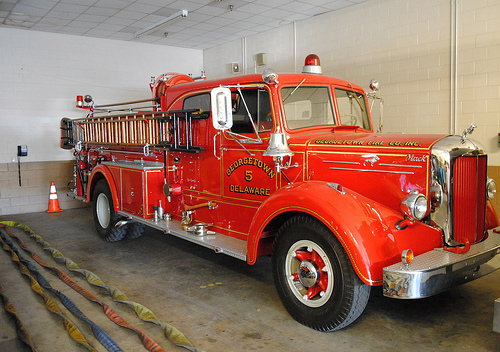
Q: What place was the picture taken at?
A: It was taken at the garage.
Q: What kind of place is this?
A: It is a garage.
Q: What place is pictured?
A: It is a garage.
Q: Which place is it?
A: It is a garage.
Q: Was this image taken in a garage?
A: Yes, it was taken in a garage.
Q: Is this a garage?
A: Yes, it is a garage.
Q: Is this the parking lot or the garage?
A: It is the garage.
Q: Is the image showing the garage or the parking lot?
A: It is showing the garage.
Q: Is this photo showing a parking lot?
A: No, the picture is showing a garage.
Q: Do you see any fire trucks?
A: Yes, there is a fire truck.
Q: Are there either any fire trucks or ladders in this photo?
A: Yes, there is a fire truck.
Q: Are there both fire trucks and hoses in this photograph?
A: Yes, there are both a fire truck and a hose.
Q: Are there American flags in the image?
A: No, there are no American flags.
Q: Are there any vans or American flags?
A: No, there are no American flags or vans.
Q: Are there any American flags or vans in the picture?
A: No, there are no American flags or vans.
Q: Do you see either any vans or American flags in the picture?
A: No, there are no American flags or vans.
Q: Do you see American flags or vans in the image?
A: No, there are no American flags or vans.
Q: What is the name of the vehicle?
A: The vehicle is a fire truck.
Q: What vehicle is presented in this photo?
A: The vehicle is a fire truck.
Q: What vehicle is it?
A: The vehicle is a fire truck.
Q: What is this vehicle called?
A: This is a fire truck.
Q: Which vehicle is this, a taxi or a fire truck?
A: This is a fire truck.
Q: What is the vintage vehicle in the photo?
A: The vehicle is a fire truck.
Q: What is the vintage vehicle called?
A: The vehicle is a fire truck.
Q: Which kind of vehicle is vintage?
A: The vehicle is a fire truck.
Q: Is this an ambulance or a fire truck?
A: This is a fire truck.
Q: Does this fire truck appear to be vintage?
A: Yes, the fire truck is vintage.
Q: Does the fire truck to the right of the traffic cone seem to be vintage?
A: Yes, the fire truck is vintage.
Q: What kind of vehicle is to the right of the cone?
A: The vehicle is a fire truck.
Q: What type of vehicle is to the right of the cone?
A: The vehicle is a fire truck.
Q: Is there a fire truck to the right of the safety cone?
A: Yes, there is a fire truck to the right of the safety cone.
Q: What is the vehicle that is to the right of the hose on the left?
A: The vehicle is a fire truck.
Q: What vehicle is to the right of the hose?
A: The vehicle is a fire truck.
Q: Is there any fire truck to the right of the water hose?
A: Yes, there is a fire truck to the right of the water hose.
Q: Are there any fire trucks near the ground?
A: Yes, there is a fire truck near the ground.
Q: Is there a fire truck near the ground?
A: Yes, there is a fire truck near the ground.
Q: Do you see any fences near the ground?
A: No, there is a fire truck near the ground.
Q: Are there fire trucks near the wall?
A: Yes, there is a fire truck near the wall.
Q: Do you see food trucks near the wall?
A: No, there is a fire truck near the wall.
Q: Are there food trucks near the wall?
A: No, there is a fire truck near the wall.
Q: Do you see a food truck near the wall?
A: No, there is a fire truck near the wall.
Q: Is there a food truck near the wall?
A: No, there is a fire truck near the wall.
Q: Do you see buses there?
A: No, there are no buses.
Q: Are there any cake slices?
A: No, there are no cake slices.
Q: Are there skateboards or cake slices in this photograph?
A: No, there are no cake slices or skateboards.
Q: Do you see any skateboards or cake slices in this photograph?
A: No, there are no cake slices or skateboards.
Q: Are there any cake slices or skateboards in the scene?
A: No, there are no cake slices or skateboards.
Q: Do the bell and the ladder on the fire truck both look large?
A: Yes, both the bell and the ladder are large.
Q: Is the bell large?
A: Yes, the bell is large.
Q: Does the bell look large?
A: Yes, the bell is large.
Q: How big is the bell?
A: The bell is large.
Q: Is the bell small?
A: No, the bell is large.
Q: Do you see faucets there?
A: No, there are no faucets.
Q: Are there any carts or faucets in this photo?
A: No, there are no faucets or carts.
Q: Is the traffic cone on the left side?
A: Yes, the traffic cone is on the left of the image.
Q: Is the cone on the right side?
A: No, the cone is on the left of the image.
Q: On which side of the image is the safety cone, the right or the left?
A: The safety cone is on the left of the image.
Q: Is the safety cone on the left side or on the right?
A: The safety cone is on the left of the image.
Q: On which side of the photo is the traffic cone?
A: The traffic cone is on the left of the image.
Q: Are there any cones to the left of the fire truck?
A: Yes, there is a cone to the left of the fire truck.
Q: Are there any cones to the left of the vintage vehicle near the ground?
A: Yes, there is a cone to the left of the fire truck.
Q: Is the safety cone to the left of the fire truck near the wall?
A: Yes, the safety cone is to the left of the fire truck.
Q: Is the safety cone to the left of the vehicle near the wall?
A: Yes, the safety cone is to the left of the fire truck.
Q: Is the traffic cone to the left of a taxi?
A: No, the traffic cone is to the left of the fire truck.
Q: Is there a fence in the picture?
A: No, there are no fences.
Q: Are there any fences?
A: No, there are no fences.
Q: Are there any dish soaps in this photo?
A: No, there are no dish soaps.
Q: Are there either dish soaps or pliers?
A: No, there are no dish soaps or pliers.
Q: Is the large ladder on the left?
A: Yes, the ladder is on the left of the image.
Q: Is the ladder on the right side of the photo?
A: No, the ladder is on the left of the image.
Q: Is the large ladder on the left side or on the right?
A: The ladder is on the left of the image.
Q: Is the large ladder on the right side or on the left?
A: The ladder is on the left of the image.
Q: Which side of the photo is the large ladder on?
A: The ladder is on the left of the image.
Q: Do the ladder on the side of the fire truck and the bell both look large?
A: Yes, both the ladder and the bell are large.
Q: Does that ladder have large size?
A: Yes, the ladder is large.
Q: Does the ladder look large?
A: Yes, the ladder is large.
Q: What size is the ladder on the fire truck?
A: The ladder is large.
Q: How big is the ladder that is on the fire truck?
A: The ladder is large.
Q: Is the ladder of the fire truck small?
A: No, the ladder is large.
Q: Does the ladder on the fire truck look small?
A: No, the ladder is large.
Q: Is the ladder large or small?
A: The ladder is large.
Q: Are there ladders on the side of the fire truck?
A: Yes, there is a ladder on the side of the fire truck.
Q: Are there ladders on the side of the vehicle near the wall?
A: Yes, there is a ladder on the side of the fire truck.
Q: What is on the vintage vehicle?
A: The ladder is on the fire truck.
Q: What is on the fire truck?
A: The ladder is on the fire truck.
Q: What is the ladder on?
A: The ladder is on the fire truck.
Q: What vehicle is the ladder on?
A: The ladder is on the fire truck.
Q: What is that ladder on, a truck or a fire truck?
A: The ladder is on a fire truck.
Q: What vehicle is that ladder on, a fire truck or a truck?
A: The ladder is on a fire truck.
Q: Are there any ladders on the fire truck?
A: Yes, there is a ladder on the fire truck.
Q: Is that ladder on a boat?
A: No, the ladder is on the fire truck.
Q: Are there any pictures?
A: No, there are no pictures.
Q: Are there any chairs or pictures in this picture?
A: No, there are no pictures or chairs.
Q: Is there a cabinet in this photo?
A: No, there are no cabinets.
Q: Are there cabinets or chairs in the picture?
A: No, there are no cabinets or chairs.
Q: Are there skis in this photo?
A: No, there are no skis.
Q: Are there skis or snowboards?
A: No, there are no skis or snowboards.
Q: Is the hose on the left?
A: Yes, the hose is on the left of the image.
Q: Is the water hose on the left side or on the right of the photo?
A: The water hose is on the left of the image.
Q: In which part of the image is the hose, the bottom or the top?
A: The hose is in the bottom of the image.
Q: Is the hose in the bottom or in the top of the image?
A: The hose is in the bottom of the image.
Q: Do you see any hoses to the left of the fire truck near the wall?
A: Yes, there is a hose to the left of the fire truck.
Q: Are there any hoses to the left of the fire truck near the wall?
A: Yes, there is a hose to the left of the fire truck.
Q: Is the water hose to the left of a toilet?
A: No, the water hose is to the left of a fire truck.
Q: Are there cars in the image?
A: No, there are no cars.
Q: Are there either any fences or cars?
A: No, there are no cars or fences.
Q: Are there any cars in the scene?
A: No, there are no cars.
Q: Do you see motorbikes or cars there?
A: No, there are no cars or motorbikes.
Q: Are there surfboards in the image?
A: No, there are no surfboards.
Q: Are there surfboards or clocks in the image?
A: No, there are no surfboards or clocks.